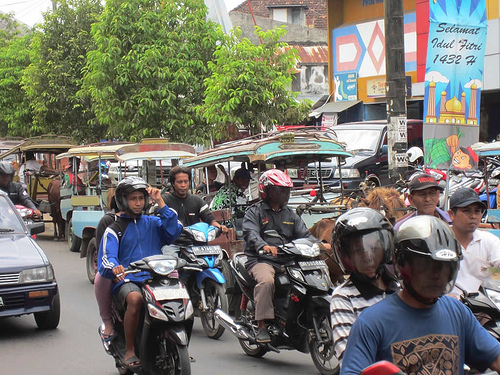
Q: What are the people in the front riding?
A: Motorcycles.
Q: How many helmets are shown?
A: Four.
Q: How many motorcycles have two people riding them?
A: Three.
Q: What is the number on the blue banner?
A: 1432.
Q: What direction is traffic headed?
A: Right.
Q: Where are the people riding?
A: City street.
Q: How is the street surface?
A: Paved.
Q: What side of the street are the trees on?
A: Right side.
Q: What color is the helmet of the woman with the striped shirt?
A: Black.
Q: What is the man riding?
A: Motorcycle.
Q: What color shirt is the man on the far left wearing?
A: Blue.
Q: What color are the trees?
A: Green.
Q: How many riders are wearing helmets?
A: Four.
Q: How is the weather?
A: Dry.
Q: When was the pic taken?
A: During the day.